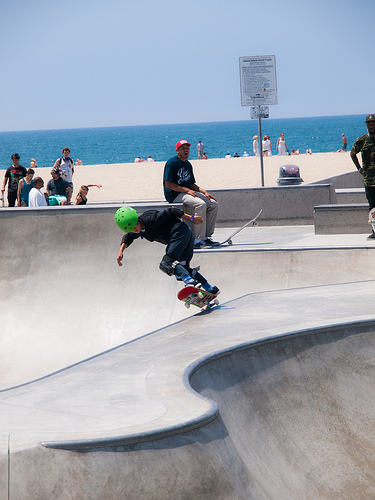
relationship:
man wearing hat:
[159, 135, 223, 257] [172, 137, 191, 151]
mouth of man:
[181, 152, 191, 157] [159, 135, 223, 257]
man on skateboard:
[159, 135, 223, 257] [192, 204, 268, 255]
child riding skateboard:
[110, 197, 220, 296] [175, 282, 224, 313]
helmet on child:
[110, 204, 142, 234] [110, 197, 220, 296]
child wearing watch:
[110, 197, 220, 296] [188, 213, 196, 226]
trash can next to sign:
[270, 157, 302, 185] [235, 48, 286, 123]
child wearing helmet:
[110, 197, 220, 296] [110, 204, 142, 234]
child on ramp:
[110, 197, 220, 296] [2, 209, 374, 387]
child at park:
[110, 197, 220, 296] [1, 157, 373, 499]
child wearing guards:
[110, 197, 220, 296] [152, 255, 184, 280]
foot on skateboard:
[202, 231, 218, 246] [192, 204, 268, 255]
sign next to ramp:
[235, 48, 286, 123] [2, 209, 374, 387]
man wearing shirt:
[159, 135, 223, 257] [161, 156, 201, 206]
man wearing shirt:
[346, 111, 374, 241] [351, 131, 375, 187]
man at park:
[159, 135, 223, 257] [1, 157, 373, 499]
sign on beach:
[235, 48, 286, 123] [2, 148, 374, 210]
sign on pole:
[235, 48, 286, 123] [255, 116, 267, 188]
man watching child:
[346, 111, 374, 241] [110, 197, 220, 296]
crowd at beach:
[219, 129, 310, 163] [2, 148, 374, 210]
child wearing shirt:
[110, 197, 220, 296] [115, 200, 193, 249]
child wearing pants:
[110, 197, 220, 296] [156, 221, 209, 288]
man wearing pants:
[159, 135, 223, 257] [171, 183, 220, 243]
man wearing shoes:
[159, 135, 223, 257] [195, 234, 221, 252]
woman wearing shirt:
[259, 134, 272, 157] [261, 138, 271, 150]